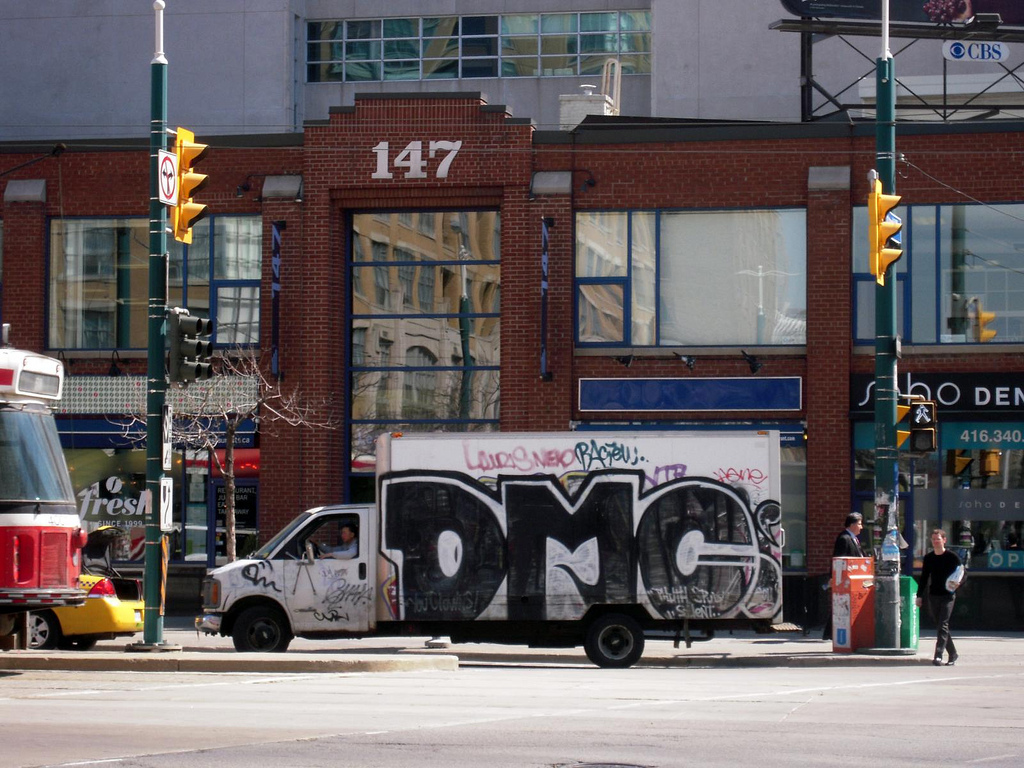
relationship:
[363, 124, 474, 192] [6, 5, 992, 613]
number on front of building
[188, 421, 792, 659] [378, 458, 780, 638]
truck covered in graffiti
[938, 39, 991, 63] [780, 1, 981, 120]
cbs sign under billboard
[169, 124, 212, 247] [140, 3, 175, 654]
traffic light on pole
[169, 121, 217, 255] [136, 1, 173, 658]
traffic light on pole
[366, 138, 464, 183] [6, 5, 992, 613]
number on building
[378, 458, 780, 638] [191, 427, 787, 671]
graffiti on truck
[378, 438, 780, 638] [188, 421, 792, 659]
graffiti on truck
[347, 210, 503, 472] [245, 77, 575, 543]
wall on building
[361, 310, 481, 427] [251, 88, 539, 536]
wall on building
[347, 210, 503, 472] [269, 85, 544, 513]
wall on building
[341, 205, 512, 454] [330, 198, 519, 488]
reflection on window